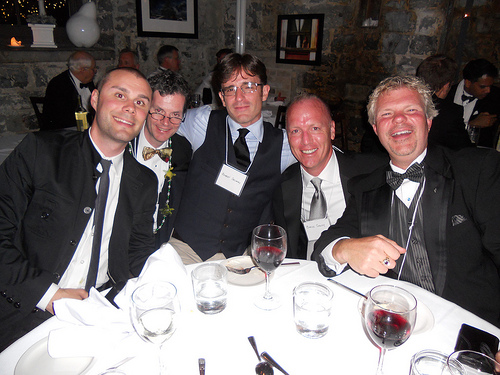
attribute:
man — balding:
[259, 87, 374, 267]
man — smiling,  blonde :
[321, 75, 499, 326]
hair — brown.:
[210, 52, 273, 125]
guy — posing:
[174, 48, 296, 258]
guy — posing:
[2, 65, 154, 350]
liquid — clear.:
[192, 292, 224, 317]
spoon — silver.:
[225, 326, 288, 373]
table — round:
[82, 244, 444, 373]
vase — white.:
[69, 3, 103, 50]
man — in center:
[177, 55, 286, 263]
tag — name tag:
[214, 160, 246, 195]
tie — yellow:
[141, 145, 172, 161]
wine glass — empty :
[167, 222, 367, 344]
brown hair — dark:
[215, 63, 270, 82]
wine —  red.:
[367, 307, 412, 347]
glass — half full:
[245, 220, 288, 306]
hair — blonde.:
[362, 78, 446, 123]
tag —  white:
[207, 160, 253, 201]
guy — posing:
[121, 83, 196, 273]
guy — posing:
[256, 96, 373, 259]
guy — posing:
[303, 76, 498, 326]